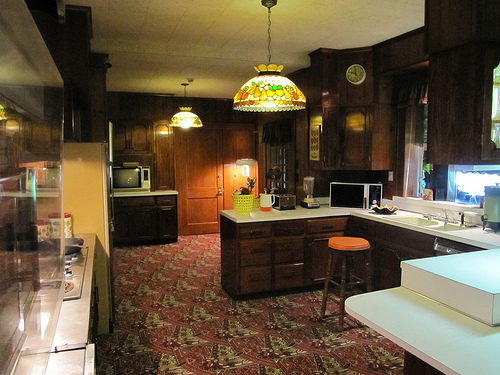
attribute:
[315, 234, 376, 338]
stool — brown, orange, sitting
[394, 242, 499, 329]
box — white, large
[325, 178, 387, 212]
microwave — black, white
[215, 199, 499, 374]
counter — white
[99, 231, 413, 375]
carpet — red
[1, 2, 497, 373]
kitchen — setting, carpeted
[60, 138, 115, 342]
refrigerator — yellow, white, closed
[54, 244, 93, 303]
stove top — electric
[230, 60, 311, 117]
ceiling light — colorful, hanging, decorated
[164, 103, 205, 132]
ceiling light — colorful, hanging, decorated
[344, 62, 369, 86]
clock — white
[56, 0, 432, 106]
ceiling — white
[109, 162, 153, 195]
tv — white, old, gray, off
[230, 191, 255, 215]
basket — yellow, plastic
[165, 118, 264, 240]
door — wooden, brown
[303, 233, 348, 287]
cabinet — brown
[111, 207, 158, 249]
cabinet — brown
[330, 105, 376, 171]
cabinet — brown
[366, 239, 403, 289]
cabinet — brown